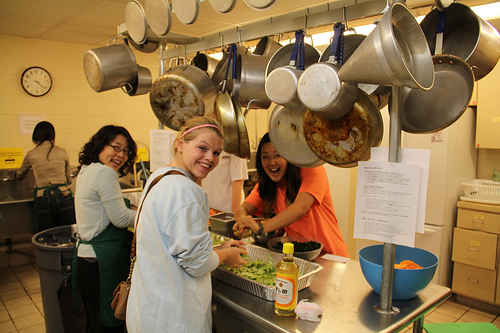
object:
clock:
[19, 65, 53, 97]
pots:
[82, 35, 138, 94]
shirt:
[244, 165, 350, 257]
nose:
[200, 149, 214, 162]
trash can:
[32, 224, 89, 332]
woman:
[14, 120, 75, 232]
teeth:
[196, 161, 210, 168]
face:
[180, 129, 224, 180]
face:
[259, 140, 288, 182]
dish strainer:
[460, 178, 500, 202]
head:
[173, 114, 226, 179]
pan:
[212, 43, 237, 155]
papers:
[352, 160, 422, 250]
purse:
[109, 168, 190, 322]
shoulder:
[167, 169, 203, 199]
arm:
[257, 165, 327, 235]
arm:
[94, 167, 138, 230]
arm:
[14, 152, 31, 182]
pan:
[264, 28, 305, 109]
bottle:
[273, 242, 299, 318]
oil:
[274, 257, 299, 317]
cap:
[279, 242, 297, 253]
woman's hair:
[77, 124, 140, 180]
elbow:
[181, 254, 213, 279]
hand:
[223, 246, 250, 269]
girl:
[124, 113, 249, 333]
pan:
[148, 55, 215, 132]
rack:
[160, 0, 438, 62]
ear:
[174, 135, 184, 154]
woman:
[0, 120, 55, 250]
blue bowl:
[356, 242, 439, 302]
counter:
[213, 252, 457, 332]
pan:
[386, 52, 480, 136]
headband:
[180, 123, 225, 138]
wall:
[2, 36, 163, 169]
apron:
[69, 196, 135, 333]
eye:
[196, 144, 207, 152]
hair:
[172, 114, 225, 156]